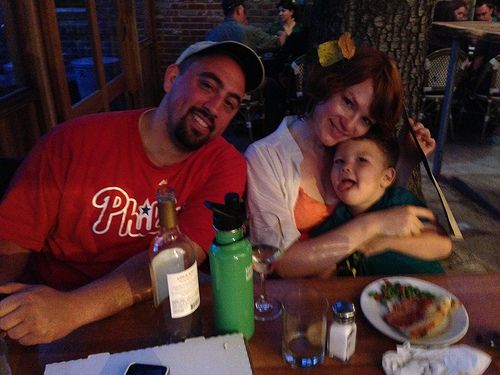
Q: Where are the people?
A: At a restaurant.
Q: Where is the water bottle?
A: On the table.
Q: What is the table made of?
A: Wood.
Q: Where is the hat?
A: On the man's head.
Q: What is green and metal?
A: A water bottle.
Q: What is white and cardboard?
A: A pizza box.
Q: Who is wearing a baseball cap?
A: A man.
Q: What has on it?
A: A plate.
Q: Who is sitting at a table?
A: A man.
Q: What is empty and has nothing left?
A: A liquor bottle.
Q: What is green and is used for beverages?
A: A bottle.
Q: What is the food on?
A: A plate.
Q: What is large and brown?
A: A dining table.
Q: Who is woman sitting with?
A: Child.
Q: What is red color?
A: Tshirt.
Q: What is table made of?
A: Wood.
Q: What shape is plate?
A: Round.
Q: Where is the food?
A: On plate.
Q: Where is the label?
A: On bottle.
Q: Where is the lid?
A: Thermos.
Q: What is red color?
A: Shirt.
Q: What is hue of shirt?
A: Red.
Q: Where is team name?
A: On shirt.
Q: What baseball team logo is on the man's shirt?
A: Phillies.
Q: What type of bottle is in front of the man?
A: Wine.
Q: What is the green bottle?
A: Water bottle.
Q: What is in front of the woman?
A: Food.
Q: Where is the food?
A: The plate.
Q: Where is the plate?
A: On the table.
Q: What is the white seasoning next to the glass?
A: Salt.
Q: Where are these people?
A: A Restaurant.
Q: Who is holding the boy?
A: The Woman.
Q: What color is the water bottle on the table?
A: Green.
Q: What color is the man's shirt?
A: Red.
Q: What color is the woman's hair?
A: Red.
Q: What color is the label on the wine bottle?
A: White.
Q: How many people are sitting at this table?
A: 3.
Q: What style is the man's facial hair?
A: Beard.